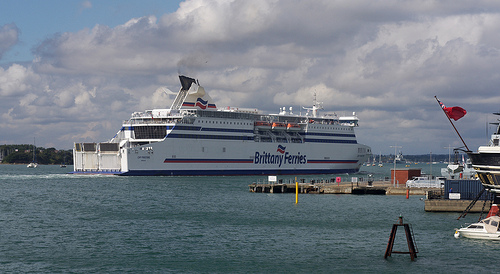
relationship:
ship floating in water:
[71, 75, 359, 174] [1, 163, 500, 274]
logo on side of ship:
[254, 143, 308, 166] [71, 75, 359, 174]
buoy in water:
[385, 217, 419, 260] [1, 163, 500, 274]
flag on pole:
[439, 103, 466, 122] [432, 94, 472, 155]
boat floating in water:
[57, 162, 67, 168] [1, 163, 500, 274]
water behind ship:
[1, 172, 116, 182] [71, 75, 359, 174]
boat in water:
[57, 162, 67, 168] [1, 163, 500, 274]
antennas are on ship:
[277, 90, 323, 116] [71, 75, 359, 174]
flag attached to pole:
[439, 103, 466, 122] [432, 94, 472, 155]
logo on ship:
[254, 143, 308, 166] [71, 75, 359, 174]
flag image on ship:
[276, 144, 288, 156] [71, 75, 359, 174]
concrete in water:
[421, 198, 492, 211] [1, 163, 500, 274]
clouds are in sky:
[0, 1, 499, 155] [1, 1, 498, 155]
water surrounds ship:
[1, 163, 500, 274] [71, 75, 359, 174]